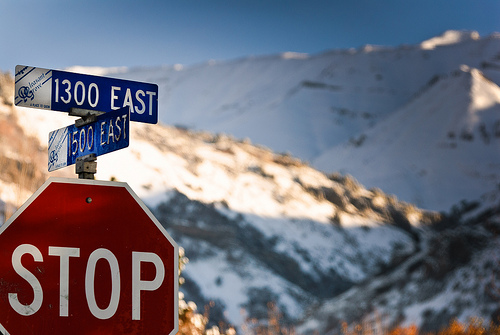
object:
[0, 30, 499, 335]
snow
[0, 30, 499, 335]
mountains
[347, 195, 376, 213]
rocks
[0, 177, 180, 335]
stop sign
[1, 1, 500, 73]
sky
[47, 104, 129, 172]
street sign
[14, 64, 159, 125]
street sign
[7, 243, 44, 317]
letter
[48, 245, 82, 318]
letter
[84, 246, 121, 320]
letter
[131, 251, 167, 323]
letter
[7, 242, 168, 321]
stop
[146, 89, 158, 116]
letters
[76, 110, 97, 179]
pole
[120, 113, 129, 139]
letters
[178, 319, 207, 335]
leaves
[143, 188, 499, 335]
shadow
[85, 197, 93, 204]
bolt